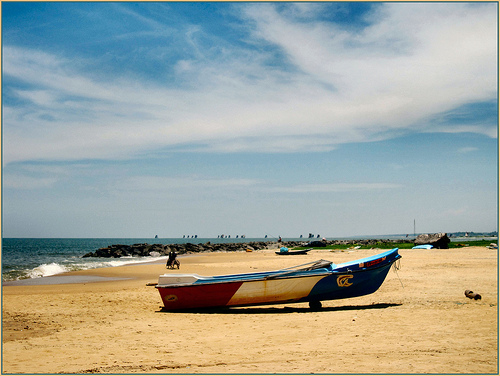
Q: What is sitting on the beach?
A: A boat sitting on the beach.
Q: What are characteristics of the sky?
A: The sky is blue and white.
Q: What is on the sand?
A: Canoe on the sand.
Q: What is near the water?
A: Rocks near the beach.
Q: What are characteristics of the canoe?
A: Red, blue , and white canoe.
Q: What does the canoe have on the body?
A: Dirt.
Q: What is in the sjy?
A: Clouds.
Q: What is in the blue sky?
A: Clouds.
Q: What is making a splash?
A: Waves.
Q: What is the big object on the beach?
A: A boat.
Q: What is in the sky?
A: Clouds.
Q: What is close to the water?
A: A jetty.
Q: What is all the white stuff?
A: Clouds.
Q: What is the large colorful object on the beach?
A: A boat.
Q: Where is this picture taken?
A: At a beach.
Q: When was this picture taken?
A: Daytime.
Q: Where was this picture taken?
A: The beach.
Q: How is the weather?
A: Clear.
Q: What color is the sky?
A: Blue.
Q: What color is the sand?
A: Brown.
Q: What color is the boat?
A: Red, white and blue.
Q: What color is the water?
A: Aqua.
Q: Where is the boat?
A: On the beach.